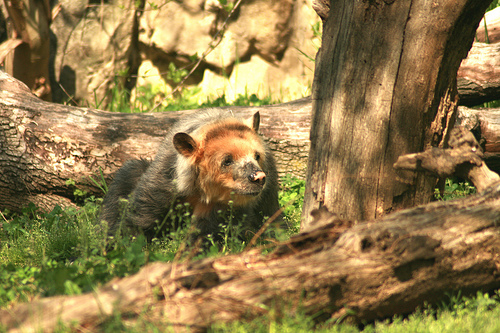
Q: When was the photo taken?
A: Daytime.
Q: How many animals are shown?
A: One.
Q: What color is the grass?
A: Green.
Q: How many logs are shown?
A: Three.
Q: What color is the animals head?
A: Brown.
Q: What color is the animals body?
A: Gray.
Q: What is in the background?
A: Rocks.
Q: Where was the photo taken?
A: At the zoo.